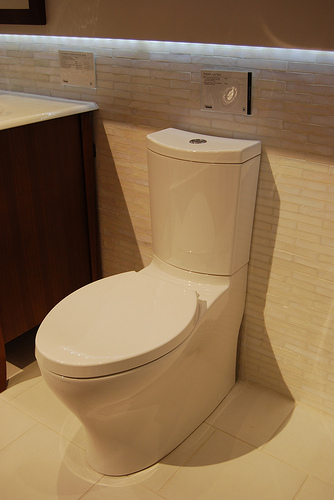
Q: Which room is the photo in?
A: It is at the bathroom.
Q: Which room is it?
A: It is a bathroom.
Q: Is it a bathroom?
A: Yes, it is a bathroom.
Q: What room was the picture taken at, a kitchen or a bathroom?
A: It was taken at a bathroom.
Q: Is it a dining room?
A: No, it is a bathroom.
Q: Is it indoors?
A: Yes, it is indoors.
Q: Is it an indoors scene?
A: Yes, it is indoors.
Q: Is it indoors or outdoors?
A: It is indoors.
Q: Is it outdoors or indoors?
A: It is indoors.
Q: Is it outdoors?
A: No, it is indoors.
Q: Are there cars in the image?
A: No, there are no cars.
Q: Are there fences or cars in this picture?
A: No, there are no cars or fences.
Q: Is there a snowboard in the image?
A: No, there are no snowboards.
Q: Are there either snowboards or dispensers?
A: No, there are no snowboards or dispensers.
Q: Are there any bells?
A: No, there are no bells.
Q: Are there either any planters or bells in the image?
A: No, there are no bells or planters.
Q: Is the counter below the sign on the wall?
A: Yes, the counter is below the sign.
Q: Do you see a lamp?
A: No, there are no lamps.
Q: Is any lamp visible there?
A: No, there are no lamps.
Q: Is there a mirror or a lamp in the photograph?
A: No, there are no lamps or mirrors.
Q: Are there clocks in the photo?
A: No, there are no clocks.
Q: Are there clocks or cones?
A: No, there are no clocks or cones.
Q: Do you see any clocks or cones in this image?
A: No, there are no clocks or cones.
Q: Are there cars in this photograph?
A: No, there are no cars.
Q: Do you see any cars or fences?
A: No, there are no cars or fences.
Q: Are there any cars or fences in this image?
A: No, there are no cars or fences.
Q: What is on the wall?
A: The sign is on the wall.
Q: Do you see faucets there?
A: No, there are no faucets.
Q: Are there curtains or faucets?
A: No, there are no faucets or curtains.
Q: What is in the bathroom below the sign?
A: The toilet is in the bathroom.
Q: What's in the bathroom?
A: The toilet is in the bathroom.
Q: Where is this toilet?
A: The toilet is in the bathroom.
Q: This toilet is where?
A: The toilet is in the bathroom.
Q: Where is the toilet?
A: The toilet is in the bathroom.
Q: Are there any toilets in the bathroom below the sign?
A: Yes, there is a toilet in the bathroom.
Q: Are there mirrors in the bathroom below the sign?
A: No, there is a toilet in the bathroom.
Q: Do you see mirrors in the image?
A: No, there are no mirrors.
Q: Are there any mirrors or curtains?
A: No, there are no mirrors or curtains.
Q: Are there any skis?
A: No, there are no skis.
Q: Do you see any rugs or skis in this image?
A: No, there are no skis or rugs.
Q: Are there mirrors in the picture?
A: No, there are no mirrors.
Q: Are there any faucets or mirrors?
A: No, there are no mirrors or faucets.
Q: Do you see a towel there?
A: No, there are no towels.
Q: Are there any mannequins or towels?
A: No, there are no towels or mannequins.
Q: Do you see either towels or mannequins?
A: No, there are no towels or mannequins.